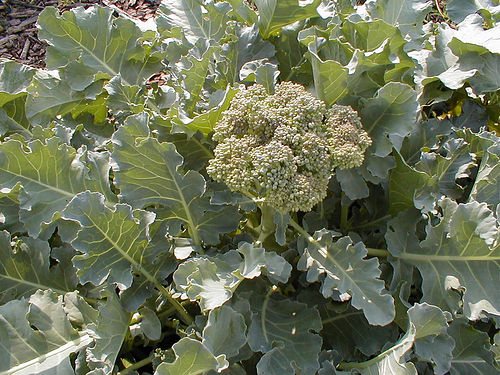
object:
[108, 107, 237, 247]
leaf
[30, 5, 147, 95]
leaf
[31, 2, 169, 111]
leaf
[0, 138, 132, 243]
leaf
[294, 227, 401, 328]
leaf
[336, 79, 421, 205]
leaf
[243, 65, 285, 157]
ground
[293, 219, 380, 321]
stem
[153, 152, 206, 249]
stem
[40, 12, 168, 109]
stem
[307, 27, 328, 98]
stem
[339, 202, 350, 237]
stem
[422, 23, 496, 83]
stem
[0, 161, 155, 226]
stem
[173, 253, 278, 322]
leaf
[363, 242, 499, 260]
stem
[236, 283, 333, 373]
leaf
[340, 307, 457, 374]
leaf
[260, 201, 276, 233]
stalk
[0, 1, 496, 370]
bush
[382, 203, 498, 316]
green leaf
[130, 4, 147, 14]
sticks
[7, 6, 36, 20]
sticks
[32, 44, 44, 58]
sticks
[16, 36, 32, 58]
sticks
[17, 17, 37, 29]
sticks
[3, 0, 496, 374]
cauliflower plant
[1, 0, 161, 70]
soil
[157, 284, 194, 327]
stem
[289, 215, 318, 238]
stem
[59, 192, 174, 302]
leaf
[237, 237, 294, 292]
leaf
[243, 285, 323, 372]
leaf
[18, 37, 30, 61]
wood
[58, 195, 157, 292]
leaf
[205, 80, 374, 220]
cailiflower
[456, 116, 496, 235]
green leaves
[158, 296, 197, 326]
stem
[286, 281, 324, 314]
shade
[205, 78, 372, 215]
plant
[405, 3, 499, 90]
leaves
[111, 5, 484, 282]
sunlight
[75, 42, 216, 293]
tree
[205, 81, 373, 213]
brocolli